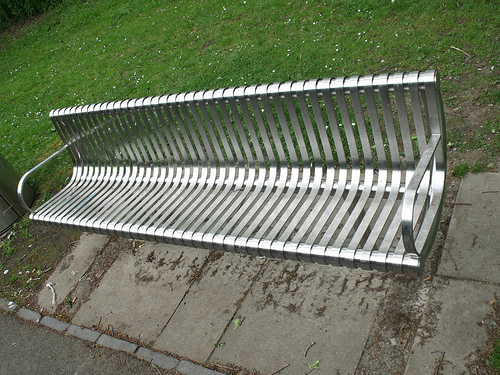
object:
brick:
[135, 345, 179, 373]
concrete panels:
[149, 247, 266, 363]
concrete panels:
[405, 276, 499, 373]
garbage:
[38, 281, 60, 308]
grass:
[5, 4, 498, 69]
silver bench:
[14, 69, 449, 279]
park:
[0, 0, 498, 374]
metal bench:
[15, 59, 455, 279]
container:
[0, 142, 32, 238]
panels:
[147, 252, 254, 365]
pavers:
[33, 230, 433, 372]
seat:
[13, 63, 447, 278]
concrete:
[20, 327, 231, 364]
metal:
[400, 162, 417, 255]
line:
[354, 310, 379, 341]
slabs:
[55, 182, 499, 367]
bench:
[15, 80, 455, 291]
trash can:
[0, 153, 35, 240]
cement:
[25, 239, 367, 370]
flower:
[311, 20, 317, 25]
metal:
[111, 173, 174, 247]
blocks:
[109, 243, 190, 332]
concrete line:
[41, 238, 117, 313]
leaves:
[14, 239, 63, 300]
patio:
[10, 25, 488, 369]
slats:
[26, 57, 460, 297]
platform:
[63, 170, 495, 368]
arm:
[399, 131, 447, 259]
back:
[43, 57, 461, 182]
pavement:
[0, 304, 170, 373]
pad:
[22, 158, 500, 371]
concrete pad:
[35, 169, 497, 369]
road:
[4, 301, 181, 367]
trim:
[10, 291, 175, 357]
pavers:
[0, 12, 499, 370]